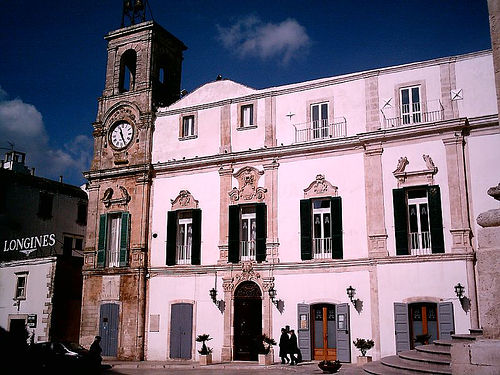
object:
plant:
[195, 333, 214, 355]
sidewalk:
[113, 360, 255, 370]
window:
[14, 270, 30, 301]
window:
[337, 314, 346, 329]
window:
[299, 313, 308, 329]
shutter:
[392, 187, 410, 255]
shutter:
[330, 196, 343, 260]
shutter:
[255, 202, 267, 263]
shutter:
[226, 204, 240, 264]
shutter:
[191, 207, 202, 265]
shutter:
[164, 209, 179, 266]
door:
[308, 303, 338, 363]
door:
[407, 302, 440, 351]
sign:
[3, 233, 56, 257]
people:
[288, 329, 300, 365]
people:
[278, 328, 290, 365]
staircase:
[364, 331, 484, 374]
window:
[405, 189, 432, 255]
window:
[311, 198, 333, 260]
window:
[238, 203, 257, 262]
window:
[175, 210, 193, 265]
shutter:
[425, 184, 445, 254]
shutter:
[299, 199, 313, 261]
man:
[88, 335, 104, 375]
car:
[0, 339, 105, 374]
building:
[78, 0, 500, 364]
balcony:
[379, 98, 445, 129]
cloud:
[214, 10, 316, 70]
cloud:
[0, 89, 91, 180]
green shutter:
[119, 211, 130, 267]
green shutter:
[96, 213, 107, 268]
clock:
[108, 119, 134, 150]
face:
[111, 123, 133, 148]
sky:
[2, 0, 492, 188]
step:
[360, 359, 451, 375]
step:
[379, 345, 451, 374]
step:
[451, 328, 483, 340]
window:
[240, 103, 254, 127]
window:
[181, 114, 195, 137]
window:
[309, 101, 330, 140]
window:
[399, 83, 424, 126]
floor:
[151, 43, 498, 173]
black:
[280, 332, 286, 363]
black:
[290, 339, 297, 349]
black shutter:
[166, 208, 201, 265]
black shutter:
[227, 202, 268, 263]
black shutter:
[299, 196, 343, 261]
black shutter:
[391, 183, 445, 256]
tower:
[77, 0, 188, 360]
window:
[96, 209, 131, 268]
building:
[0, 233, 82, 351]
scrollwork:
[221, 262, 275, 292]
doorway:
[231, 279, 265, 365]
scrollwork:
[227, 165, 267, 204]